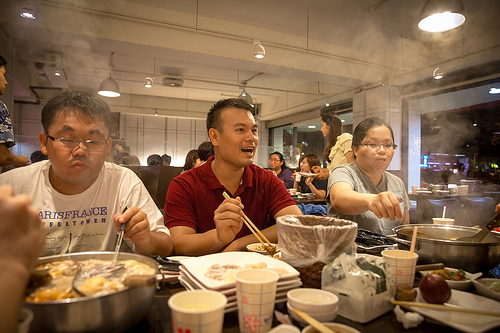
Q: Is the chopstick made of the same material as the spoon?
A: No, the chopstick is made of wood and the spoon is made of metal.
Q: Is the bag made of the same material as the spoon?
A: No, the bag is made of plastic and the spoon is made of metal.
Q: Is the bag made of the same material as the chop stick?
A: No, the bag is made of plastic and the chop stick is made of wood.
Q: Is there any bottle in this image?
A: No, there are no bottles.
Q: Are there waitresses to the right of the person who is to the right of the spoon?
A: Yes, there is a waitress to the right of the person.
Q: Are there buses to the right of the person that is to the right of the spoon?
A: No, there is a waitress to the right of the person.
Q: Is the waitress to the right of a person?
A: Yes, the waitress is to the right of a person.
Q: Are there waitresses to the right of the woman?
A: Yes, there is a waitress to the right of the woman.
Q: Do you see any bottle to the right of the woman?
A: No, there is a waitress to the right of the woman.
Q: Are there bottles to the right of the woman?
A: No, there is a waitress to the right of the woman.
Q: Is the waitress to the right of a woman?
A: Yes, the waitress is to the right of a woman.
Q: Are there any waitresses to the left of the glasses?
A: Yes, there is a waitress to the left of the glasses.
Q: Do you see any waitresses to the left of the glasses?
A: Yes, there is a waitress to the left of the glasses.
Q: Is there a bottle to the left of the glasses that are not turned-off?
A: No, there is a waitress to the left of the glasses.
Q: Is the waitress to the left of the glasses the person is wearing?
A: Yes, the waitress is to the left of the glasses.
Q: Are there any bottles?
A: No, there are no bottles.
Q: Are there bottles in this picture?
A: No, there are no bottles.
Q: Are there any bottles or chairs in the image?
A: No, there are no bottles or chairs.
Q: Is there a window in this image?
A: Yes, there is a window.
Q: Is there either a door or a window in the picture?
A: Yes, there is a window.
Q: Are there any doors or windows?
A: Yes, there is a window.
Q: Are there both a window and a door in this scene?
A: No, there is a window but no doors.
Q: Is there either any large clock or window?
A: Yes, there is a large window.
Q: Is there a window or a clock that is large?
A: Yes, the window is large.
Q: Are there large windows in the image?
A: Yes, there is a large window.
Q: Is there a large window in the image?
A: Yes, there is a large window.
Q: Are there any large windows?
A: Yes, there is a large window.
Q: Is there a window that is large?
A: Yes, there is a window that is large.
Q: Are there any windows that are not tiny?
A: Yes, there is a large window.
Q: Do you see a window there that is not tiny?
A: Yes, there is a large window.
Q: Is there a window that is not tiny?
A: Yes, there is a large window.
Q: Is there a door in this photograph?
A: No, there are no doors.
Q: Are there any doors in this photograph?
A: No, there are no doors.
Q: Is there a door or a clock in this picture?
A: No, there are no doors or clocks.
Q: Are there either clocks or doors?
A: No, there are no doors or clocks.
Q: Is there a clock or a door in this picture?
A: No, there are no doors or clocks.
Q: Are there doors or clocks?
A: No, there are no doors or clocks.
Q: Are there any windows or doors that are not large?
A: No, there is a window but it is large.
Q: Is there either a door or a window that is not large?
A: No, there is a window but it is large.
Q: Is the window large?
A: Yes, the window is large.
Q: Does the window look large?
A: Yes, the window is large.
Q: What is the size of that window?
A: The window is large.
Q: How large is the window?
A: The window is large.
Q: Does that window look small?
A: No, the window is large.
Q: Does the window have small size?
A: No, the window is large.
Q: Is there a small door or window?
A: No, there is a window but it is large.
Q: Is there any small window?
A: No, there is a window but it is large.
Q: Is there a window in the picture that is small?
A: No, there is a window but it is large.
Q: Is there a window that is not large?
A: No, there is a window but it is large.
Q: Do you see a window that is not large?
A: No, there is a window but it is large.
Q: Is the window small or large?
A: The window is large.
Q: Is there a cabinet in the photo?
A: No, there are no cabinets.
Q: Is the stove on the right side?
A: Yes, the stove is on the right of the image.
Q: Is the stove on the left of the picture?
A: No, the stove is on the right of the image.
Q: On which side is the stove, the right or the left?
A: The stove is on the right of the image.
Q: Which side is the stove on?
A: The stove is on the right of the image.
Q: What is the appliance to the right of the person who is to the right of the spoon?
A: The appliance is a stove.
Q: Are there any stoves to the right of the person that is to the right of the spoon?
A: Yes, there is a stove to the right of the person.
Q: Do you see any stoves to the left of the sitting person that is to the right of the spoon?
A: No, the stove is to the right of the person.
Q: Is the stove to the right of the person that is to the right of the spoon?
A: Yes, the stove is to the right of the person.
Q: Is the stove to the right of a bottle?
A: No, the stove is to the right of the person.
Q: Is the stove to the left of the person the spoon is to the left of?
A: No, the stove is to the right of the person.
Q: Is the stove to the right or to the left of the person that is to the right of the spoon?
A: The stove is to the right of the person.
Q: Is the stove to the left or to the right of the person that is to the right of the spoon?
A: The stove is to the right of the person.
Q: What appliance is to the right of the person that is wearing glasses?
A: The appliance is a stove.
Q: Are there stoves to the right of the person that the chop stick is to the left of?
A: Yes, there is a stove to the right of the person.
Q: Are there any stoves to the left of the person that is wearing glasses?
A: No, the stove is to the right of the person.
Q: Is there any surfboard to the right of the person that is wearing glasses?
A: No, there is a stove to the right of the person.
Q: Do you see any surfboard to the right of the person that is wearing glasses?
A: No, there is a stove to the right of the person.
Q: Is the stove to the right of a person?
A: Yes, the stove is to the right of a person.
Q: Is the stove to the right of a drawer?
A: No, the stove is to the right of a person.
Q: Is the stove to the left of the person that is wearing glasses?
A: No, the stove is to the right of the person.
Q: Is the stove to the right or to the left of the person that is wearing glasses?
A: The stove is to the right of the person.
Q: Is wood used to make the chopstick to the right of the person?
A: Yes, the chopstick is made of wood.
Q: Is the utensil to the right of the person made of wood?
A: Yes, the chopstick is made of wood.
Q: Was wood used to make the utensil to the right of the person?
A: Yes, the chopstick is made of wood.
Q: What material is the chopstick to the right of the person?
A: The chopstick is made of wood.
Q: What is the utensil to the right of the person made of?
A: The chopstick is made of wood.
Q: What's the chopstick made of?
A: The chopstick is made of wood.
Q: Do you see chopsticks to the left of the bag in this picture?
A: Yes, there is a chopstick to the left of the bag.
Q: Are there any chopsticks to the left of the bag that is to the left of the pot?
A: Yes, there is a chopstick to the left of the bag.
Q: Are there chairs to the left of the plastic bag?
A: No, there is a chopstick to the left of the bag.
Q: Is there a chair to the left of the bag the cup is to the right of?
A: No, there is a chopstick to the left of the bag.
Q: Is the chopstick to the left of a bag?
A: Yes, the chopstick is to the left of a bag.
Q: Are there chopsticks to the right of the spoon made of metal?
A: Yes, there is a chopstick to the right of the spoon.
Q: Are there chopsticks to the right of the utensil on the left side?
A: Yes, there is a chopstick to the right of the spoon.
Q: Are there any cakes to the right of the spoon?
A: No, there is a chopstick to the right of the spoon.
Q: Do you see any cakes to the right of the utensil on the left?
A: No, there is a chopstick to the right of the spoon.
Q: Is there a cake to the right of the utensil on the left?
A: No, there is a chopstick to the right of the spoon.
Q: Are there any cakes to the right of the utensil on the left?
A: No, there is a chopstick to the right of the spoon.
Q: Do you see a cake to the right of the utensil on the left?
A: No, there is a chopstick to the right of the spoon.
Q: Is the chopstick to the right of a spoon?
A: Yes, the chopstick is to the right of a spoon.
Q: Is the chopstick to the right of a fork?
A: No, the chopstick is to the right of a spoon.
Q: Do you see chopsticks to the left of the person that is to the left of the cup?
A: Yes, there is a chopstick to the left of the person.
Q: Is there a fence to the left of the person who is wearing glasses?
A: No, there is a chopstick to the left of the person.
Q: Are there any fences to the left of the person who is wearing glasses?
A: No, there is a chopstick to the left of the person.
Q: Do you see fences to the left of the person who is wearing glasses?
A: No, there is a chopstick to the left of the person.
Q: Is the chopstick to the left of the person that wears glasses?
A: Yes, the chopstick is to the left of the person.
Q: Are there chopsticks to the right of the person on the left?
A: Yes, there is a chopstick to the right of the person.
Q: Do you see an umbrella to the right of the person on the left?
A: No, there is a chopstick to the right of the person.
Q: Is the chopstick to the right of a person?
A: Yes, the chopstick is to the right of a person.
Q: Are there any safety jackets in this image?
A: No, there are no safety jackets.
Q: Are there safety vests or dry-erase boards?
A: No, there are no safety vests or dry-erase boards.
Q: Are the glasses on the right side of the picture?
A: Yes, the glasses are on the right of the image.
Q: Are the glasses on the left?
A: No, the glasses are on the right of the image.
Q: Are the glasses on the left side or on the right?
A: The glasses are on the right of the image.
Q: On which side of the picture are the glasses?
A: The glasses are on the right of the image.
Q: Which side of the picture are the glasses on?
A: The glasses are on the right of the image.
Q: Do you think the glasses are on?
A: Yes, the glasses are on.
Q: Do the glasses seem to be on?
A: Yes, the glasses are on.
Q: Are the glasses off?
A: No, the glasses are on.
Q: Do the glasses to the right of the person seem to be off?
A: No, the glasses are on.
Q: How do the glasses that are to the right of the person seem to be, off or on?
A: The glasses are on.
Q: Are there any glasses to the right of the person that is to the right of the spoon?
A: Yes, there are glasses to the right of the person.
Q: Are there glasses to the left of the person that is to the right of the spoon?
A: No, the glasses are to the right of the person.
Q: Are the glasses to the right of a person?
A: Yes, the glasses are to the right of a person.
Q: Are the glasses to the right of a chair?
A: No, the glasses are to the right of a person.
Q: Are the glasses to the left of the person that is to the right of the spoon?
A: No, the glasses are to the right of the person.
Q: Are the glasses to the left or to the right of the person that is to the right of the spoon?
A: The glasses are to the right of the person.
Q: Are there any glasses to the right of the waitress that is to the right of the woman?
A: Yes, there are glasses to the right of the waitress.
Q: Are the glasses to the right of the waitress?
A: Yes, the glasses are to the right of the waitress.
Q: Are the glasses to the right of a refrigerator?
A: No, the glasses are to the right of the waitress.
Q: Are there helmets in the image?
A: No, there are no helmets.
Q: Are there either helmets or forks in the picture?
A: No, there are no helmets or forks.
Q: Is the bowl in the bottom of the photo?
A: Yes, the bowl is in the bottom of the image.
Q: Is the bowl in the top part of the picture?
A: No, the bowl is in the bottom of the image.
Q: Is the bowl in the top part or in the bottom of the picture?
A: The bowl is in the bottom of the image.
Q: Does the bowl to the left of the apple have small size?
A: Yes, the bowl is small.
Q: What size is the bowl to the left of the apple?
A: The bowl is small.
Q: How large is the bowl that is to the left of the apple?
A: The bowl is small.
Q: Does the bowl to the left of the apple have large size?
A: No, the bowl is small.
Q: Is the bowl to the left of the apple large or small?
A: The bowl is small.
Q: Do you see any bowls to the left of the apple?
A: Yes, there is a bowl to the left of the apple.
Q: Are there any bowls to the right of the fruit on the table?
A: No, the bowl is to the left of the apple.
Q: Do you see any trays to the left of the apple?
A: No, there is a bowl to the left of the apple.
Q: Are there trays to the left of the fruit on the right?
A: No, there is a bowl to the left of the apple.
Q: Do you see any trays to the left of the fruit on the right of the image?
A: No, there is a bowl to the left of the apple.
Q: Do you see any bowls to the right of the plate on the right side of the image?
A: No, the bowl is to the left of the plate.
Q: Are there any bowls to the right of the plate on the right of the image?
A: No, the bowl is to the left of the plate.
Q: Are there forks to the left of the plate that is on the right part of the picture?
A: No, there is a bowl to the left of the plate.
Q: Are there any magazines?
A: No, there are no magazines.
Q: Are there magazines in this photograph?
A: No, there are no magazines.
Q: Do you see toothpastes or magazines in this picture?
A: No, there are no magazines or toothpastes.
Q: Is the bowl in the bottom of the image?
A: Yes, the bowl is in the bottom of the image.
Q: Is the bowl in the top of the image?
A: No, the bowl is in the bottom of the image.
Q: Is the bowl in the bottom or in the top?
A: The bowl is in the bottom of the image.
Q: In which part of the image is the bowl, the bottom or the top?
A: The bowl is in the bottom of the image.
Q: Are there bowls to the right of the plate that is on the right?
A: No, the bowl is to the left of the plate.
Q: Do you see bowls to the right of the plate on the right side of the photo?
A: No, the bowl is to the left of the plate.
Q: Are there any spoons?
A: Yes, there is a spoon.